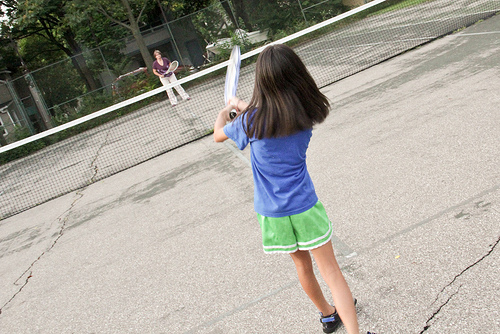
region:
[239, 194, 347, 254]
the shorts are green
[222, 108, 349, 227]
the shirt is blue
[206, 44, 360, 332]
the girl is playing tennis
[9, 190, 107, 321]
a large crack in cement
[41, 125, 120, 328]
the court is cracked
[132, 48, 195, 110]
the woman plays tennis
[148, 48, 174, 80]
the shirt is purple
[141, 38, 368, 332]
two females playing tennis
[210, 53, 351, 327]
girl wearing blue shirt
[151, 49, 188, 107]
woman wearing purple shirt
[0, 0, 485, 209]
net across the court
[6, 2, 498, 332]
concrete tennis court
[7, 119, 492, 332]
cracks in the concrete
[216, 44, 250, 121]
racket young girl is holding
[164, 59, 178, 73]
racket woman is using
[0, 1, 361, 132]
fence around the tennis court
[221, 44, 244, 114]
racket in a girl's hand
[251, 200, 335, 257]
girl's green and white shorts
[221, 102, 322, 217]
girl's blue top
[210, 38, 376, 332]
girl playing tennis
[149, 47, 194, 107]
woman playing game of tennis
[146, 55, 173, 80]
woman's purple colored top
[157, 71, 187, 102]
woman's white colored pants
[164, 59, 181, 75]
tennis racket in a woman's hand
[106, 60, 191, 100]
red vehicle parked behind a woman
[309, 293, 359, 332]
black shoe on a girl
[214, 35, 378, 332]
young girl playing tennis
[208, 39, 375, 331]
young girl wearing green shorts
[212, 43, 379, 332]
young girl wearing blue shirt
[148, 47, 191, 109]
lady playing tennis with girl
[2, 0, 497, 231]
net dividing tennis court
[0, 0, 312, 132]
chainlink fence around court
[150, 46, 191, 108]
woman wearing red shirt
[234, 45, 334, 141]
medium length dark hair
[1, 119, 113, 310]
large crack in tennis court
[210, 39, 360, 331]
girl with both hands on tennis racket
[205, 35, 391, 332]
this is a girl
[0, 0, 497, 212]
this is a net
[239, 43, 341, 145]
the girl has long hair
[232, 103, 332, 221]
this is a blue top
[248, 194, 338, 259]
the shorts are green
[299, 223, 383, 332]
the leg of a girl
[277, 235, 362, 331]
the leg of a girl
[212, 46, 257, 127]
this is a racket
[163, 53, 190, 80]
this is a racket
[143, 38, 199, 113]
This is a person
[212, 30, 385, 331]
This is a person